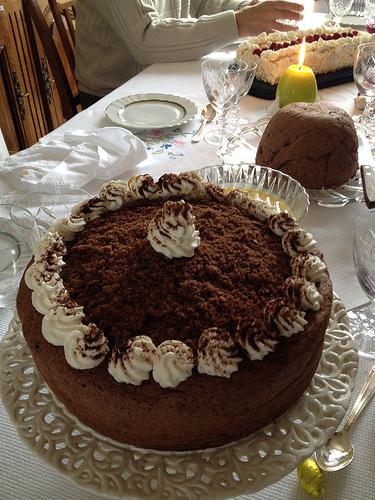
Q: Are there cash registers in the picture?
A: No, there are no cash registers.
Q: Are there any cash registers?
A: No, there are no cash registers.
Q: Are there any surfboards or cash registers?
A: No, there are no cash registers or surfboards.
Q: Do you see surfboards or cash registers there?
A: No, there are no cash registers or surfboards.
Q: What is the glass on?
A: The glass is on the table.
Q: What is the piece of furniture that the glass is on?
A: The piece of furniture is a table.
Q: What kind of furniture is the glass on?
A: The glass is on the table.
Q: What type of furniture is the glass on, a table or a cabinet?
A: The glass is on a table.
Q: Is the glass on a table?
A: Yes, the glass is on a table.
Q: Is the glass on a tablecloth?
A: No, the glass is on a table.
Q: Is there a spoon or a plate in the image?
A: Yes, there is a plate.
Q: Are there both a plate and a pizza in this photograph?
A: No, there is a plate but no pizzas.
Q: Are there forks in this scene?
A: No, there are no forks.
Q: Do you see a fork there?
A: No, there are no forks.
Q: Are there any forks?
A: No, there are no forks.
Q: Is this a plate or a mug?
A: This is a plate.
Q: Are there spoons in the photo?
A: Yes, there is a spoon.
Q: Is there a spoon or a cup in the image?
A: Yes, there is a spoon.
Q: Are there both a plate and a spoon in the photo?
A: Yes, there are both a spoon and a plate.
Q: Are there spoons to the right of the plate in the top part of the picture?
A: Yes, there is a spoon to the right of the plate.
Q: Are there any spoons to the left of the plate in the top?
A: No, the spoon is to the right of the plate.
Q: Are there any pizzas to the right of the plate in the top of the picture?
A: No, there is a spoon to the right of the plate.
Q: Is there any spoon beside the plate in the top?
A: Yes, there is a spoon beside the plate.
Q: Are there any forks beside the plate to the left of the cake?
A: No, there is a spoon beside the plate.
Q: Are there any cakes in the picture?
A: Yes, there is a cake.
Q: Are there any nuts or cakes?
A: Yes, there is a cake.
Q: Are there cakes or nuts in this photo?
A: Yes, there is a cake.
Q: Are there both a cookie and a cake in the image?
A: No, there is a cake but no cookies.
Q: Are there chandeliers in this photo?
A: No, there are no chandeliers.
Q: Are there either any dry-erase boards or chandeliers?
A: No, there are no chandeliers or dry-erase boards.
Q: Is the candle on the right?
A: Yes, the candle is on the right of the image.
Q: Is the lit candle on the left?
A: No, the candle is on the right of the image.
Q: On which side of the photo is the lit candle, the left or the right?
A: The candle is on the right of the image.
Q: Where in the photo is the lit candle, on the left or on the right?
A: The candle is on the right of the image.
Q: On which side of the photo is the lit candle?
A: The candle is on the right of the image.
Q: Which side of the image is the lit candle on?
A: The candle is on the right of the image.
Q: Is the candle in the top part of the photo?
A: Yes, the candle is in the top of the image.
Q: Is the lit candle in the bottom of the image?
A: No, the candle is in the top of the image.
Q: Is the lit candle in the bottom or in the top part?
A: The candle is in the top of the image.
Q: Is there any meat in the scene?
A: No, there is no meat.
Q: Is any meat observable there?
A: No, there is no meat.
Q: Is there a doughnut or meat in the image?
A: No, there are no meat or donuts.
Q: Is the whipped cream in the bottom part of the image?
A: Yes, the whipped cream is in the bottom of the image.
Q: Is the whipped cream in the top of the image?
A: No, the whipped cream is in the bottom of the image.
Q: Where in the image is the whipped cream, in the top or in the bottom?
A: The whipped cream is in the bottom of the image.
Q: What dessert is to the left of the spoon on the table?
A: The dessert is cakes.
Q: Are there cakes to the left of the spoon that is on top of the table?
A: Yes, there are cakes to the left of the spoon.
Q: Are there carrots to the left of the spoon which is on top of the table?
A: No, there are cakes to the left of the spoon.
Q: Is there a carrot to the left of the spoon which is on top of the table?
A: No, there are cakes to the left of the spoon.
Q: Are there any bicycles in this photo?
A: No, there are no bicycles.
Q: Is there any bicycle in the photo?
A: No, there are no bicycles.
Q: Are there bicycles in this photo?
A: No, there are no bicycles.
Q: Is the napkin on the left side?
A: Yes, the napkin is on the left of the image.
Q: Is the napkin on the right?
A: No, the napkin is on the left of the image.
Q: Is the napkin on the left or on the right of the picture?
A: The napkin is on the left of the image.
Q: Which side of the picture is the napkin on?
A: The napkin is on the left of the image.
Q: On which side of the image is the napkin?
A: The napkin is on the left of the image.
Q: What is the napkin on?
A: The napkin is on the table.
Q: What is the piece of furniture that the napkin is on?
A: The piece of furniture is a table.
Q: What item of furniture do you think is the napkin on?
A: The napkin is on the table.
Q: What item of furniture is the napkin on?
A: The napkin is on the table.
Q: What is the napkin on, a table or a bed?
A: The napkin is on a table.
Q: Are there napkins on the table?
A: Yes, there is a napkin on the table.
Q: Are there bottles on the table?
A: No, there is a napkin on the table.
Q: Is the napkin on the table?
A: Yes, the napkin is on the table.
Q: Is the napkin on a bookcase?
A: No, the napkin is on the table.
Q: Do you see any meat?
A: No, there is no meat.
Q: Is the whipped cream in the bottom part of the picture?
A: Yes, the whipped cream is in the bottom of the image.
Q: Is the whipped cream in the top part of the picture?
A: No, the whipped cream is in the bottom of the image.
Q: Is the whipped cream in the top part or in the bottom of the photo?
A: The whipped cream is in the bottom of the image.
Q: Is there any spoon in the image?
A: Yes, there is a spoon.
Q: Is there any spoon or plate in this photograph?
A: Yes, there is a spoon.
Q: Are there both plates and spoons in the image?
A: Yes, there are both a spoon and a plate.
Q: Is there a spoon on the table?
A: Yes, there is a spoon on the table.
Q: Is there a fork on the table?
A: No, there is a spoon on the table.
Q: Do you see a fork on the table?
A: No, there is a spoon on the table.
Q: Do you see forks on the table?
A: No, there is a spoon on the table.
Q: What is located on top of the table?
A: The spoon is on top of the table.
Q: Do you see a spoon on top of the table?
A: Yes, there is a spoon on top of the table.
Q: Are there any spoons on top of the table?
A: Yes, there is a spoon on top of the table.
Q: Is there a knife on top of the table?
A: No, there is a spoon on top of the table.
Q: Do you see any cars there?
A: No, there are no cars.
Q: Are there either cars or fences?
A: No, there are no cars or fences.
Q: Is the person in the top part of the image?
A: Yes, the person is in the top of the image.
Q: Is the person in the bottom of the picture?
A: No, the person is in the top of the image.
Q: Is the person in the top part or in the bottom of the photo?
A: The person is in the top of the image.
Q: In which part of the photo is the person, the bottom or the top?
A: The person is in the top of the image.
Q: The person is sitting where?
A: The person is sitting at the table.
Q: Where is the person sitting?
A: The person is sitting at the table.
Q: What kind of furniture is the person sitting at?
A: The person is sitting at the table.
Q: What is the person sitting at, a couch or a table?
A: The person is sitting at a table.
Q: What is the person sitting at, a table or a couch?
A: The person is sitting at a table.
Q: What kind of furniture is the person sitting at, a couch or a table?
A: The person is sitting at a table.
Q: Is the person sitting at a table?
A: Yes, the person is sitting at a table.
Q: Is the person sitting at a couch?
A: No, the person is sitting at a table.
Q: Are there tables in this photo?
A: Yes, there is a table.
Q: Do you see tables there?
A: Yes, there is a table.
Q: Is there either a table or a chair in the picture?
A: Yes, there is a table.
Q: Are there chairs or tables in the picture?
A: Yes, there is a table.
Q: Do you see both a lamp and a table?
A: No, there is a table but no lamps.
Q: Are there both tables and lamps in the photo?
A: No, there is a table but no lamps.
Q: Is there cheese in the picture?
A: No, there is no cheese.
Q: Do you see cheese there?
A: No, there is no cheese.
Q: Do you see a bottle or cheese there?
A: No, there are no cheese or bottles.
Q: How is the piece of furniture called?
A: The piece of furniture is a table.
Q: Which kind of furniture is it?
A: The piece of furniture is a table.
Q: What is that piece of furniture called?
A: This is a table.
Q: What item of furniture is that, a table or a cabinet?
A: This is a table.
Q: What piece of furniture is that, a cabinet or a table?
A: This is a table.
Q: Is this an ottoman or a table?
A: This is a table.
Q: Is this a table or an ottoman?
A: This is a table.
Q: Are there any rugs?
A: No, there are no rugs.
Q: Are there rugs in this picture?
A: No, there are no rugs.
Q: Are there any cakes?
A: Yes, there is a cake.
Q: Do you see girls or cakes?
A: Yes, there is a cake.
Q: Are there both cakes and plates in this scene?
A: Yes, there are both a cake and a plate.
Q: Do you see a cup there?
A: No, there are no cups.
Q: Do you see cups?
A: No, there are no cups.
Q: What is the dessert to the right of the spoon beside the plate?
A: The dessert is a cake.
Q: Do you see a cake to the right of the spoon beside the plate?
A: Yes, there is a cake to the right of the spoon.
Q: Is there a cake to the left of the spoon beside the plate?
A: No, the cake is to the right of the spoon.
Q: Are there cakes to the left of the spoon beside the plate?
A: No, the cake is to the right of the spoon.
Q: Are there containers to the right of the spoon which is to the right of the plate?
A: No, there is a cake to the right of the spoon.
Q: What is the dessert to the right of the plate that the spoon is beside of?
A: The dessert is a cake.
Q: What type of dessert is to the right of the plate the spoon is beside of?
A: The dessert is a cake.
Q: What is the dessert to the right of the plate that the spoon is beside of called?
A: The dessert is a cake.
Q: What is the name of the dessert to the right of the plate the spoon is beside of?
A: The dessert is a cake.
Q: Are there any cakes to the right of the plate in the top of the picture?
A: Yes, there is a cake to the right of the plate.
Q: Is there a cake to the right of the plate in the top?
A: Yes, there is a cake to the right of the plate.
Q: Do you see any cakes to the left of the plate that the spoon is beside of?
A: No, the cake is to the right of the plate.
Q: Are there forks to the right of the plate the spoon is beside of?
A: No, there is a cake to the right of the plate.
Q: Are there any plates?
A: Yes, there is a plate.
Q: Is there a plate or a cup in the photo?
A: Yes, there is a plate.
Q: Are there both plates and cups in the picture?
A: No, there is a plate but no cups.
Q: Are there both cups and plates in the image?
A: No, there is a plate but no cups.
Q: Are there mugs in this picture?
A: No, there are no mugs.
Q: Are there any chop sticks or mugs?
A: No, there are no mugs or chop sticks.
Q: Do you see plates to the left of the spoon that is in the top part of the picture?
A: Yes, there is a plate to the left of the spoon.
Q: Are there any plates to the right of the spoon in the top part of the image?
A: No, the plate is to the left of the spoon.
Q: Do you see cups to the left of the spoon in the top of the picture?
A: No, there is a plate to the left of the spoon.